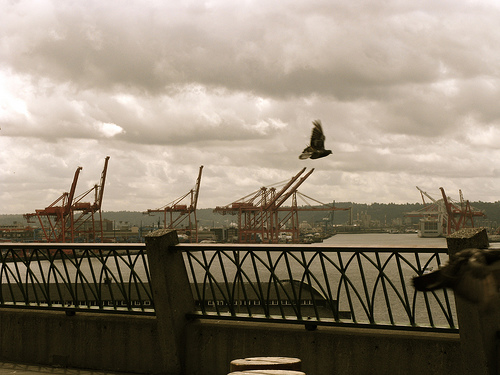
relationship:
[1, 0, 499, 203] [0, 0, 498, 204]
clouds in sky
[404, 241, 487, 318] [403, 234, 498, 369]
face on black dog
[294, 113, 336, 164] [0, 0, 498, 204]
bird in sky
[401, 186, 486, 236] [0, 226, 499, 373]
crane by bridge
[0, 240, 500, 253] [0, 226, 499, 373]
handle bars by bridge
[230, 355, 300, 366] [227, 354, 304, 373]
top of a table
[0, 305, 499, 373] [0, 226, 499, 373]
wall of bridge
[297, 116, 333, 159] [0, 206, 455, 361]
bird flying above bridge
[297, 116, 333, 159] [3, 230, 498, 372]
bird flying in front of wall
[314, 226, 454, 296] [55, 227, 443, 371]
water behind bridge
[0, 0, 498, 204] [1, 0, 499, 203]
sky covered with clouds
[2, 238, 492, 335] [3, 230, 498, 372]
railing on wall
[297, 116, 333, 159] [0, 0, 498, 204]
bird soars through sky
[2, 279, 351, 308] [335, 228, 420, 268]
dock near water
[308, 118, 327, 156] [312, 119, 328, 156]
wings are on bird